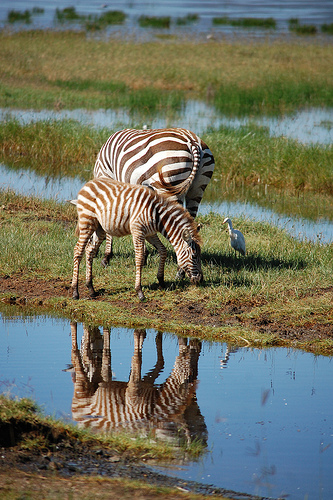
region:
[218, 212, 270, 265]
bird stand by zebra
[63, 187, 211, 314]
zebra has many stripes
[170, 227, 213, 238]
ear of striped zebra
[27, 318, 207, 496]
reflection of zebra in water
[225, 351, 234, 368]
reflection of bird in water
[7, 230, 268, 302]
green grass on muddy ground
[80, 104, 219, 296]
big zebra by small zebra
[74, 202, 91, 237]
tail of zebra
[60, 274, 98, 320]
back legs of small zebra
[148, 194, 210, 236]
man of zebra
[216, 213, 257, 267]
a white bird near a zebra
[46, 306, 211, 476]
a reflection of zebras in water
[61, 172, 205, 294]
a baby zebra eatin grass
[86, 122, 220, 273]
a mother zebra next to her baby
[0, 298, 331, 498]
water next to zebras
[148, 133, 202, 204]
a zebra tail swinging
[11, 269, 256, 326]
trampled mud next to water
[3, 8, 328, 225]
swampy ground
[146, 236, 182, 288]
a bent leg of a baby zebra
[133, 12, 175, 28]
grass protruding from water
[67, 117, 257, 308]
two zebra and a bird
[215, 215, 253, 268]
white bird standing in grass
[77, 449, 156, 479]
mud on water's edge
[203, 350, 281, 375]
ripples on water's surface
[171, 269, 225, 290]
zebra grazing on grass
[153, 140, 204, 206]
wagging tail of zebra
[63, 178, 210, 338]
young zebra next to water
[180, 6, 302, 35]
clumps of grass in water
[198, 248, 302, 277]
shado of zebra on grass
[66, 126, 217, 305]
the mother and baby zebra grazing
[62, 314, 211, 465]
the water reflection of the baby zebra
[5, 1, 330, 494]
the delta is flooded with water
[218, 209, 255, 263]
a cattle egret standing in the area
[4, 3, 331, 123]
grasses are growing by the river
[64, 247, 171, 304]
the zebra's hooves are muddy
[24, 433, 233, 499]
dark mud is on the river bank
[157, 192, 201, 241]
the zebra has a brown mane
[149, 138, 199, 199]
the tail on the zebra has long hair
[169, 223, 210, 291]
the zebra is eating grass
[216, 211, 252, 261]
white bird next to a zebra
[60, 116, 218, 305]
two zebras at the waterhole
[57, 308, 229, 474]
zebra reflection in the water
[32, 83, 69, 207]
water in the grasslands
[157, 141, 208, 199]
swishing tail of a zebra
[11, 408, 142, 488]
muddy bank of a waterhole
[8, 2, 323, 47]
green grass growing through the water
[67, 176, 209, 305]
baby zebra grazing near the water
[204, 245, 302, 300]
shadow of two zebras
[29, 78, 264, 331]
two zebras and a bird at the water hole